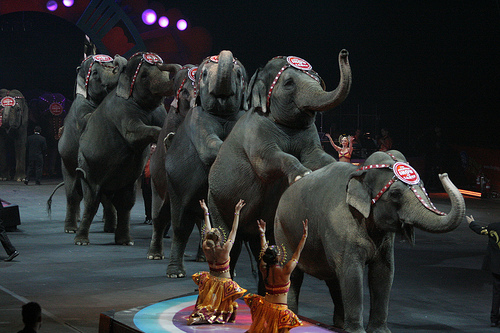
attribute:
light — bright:
[142, 9, 157, 25]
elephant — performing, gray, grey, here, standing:
[46, 53, 128, 235]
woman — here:
[196, 198, 248, 323]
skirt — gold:
[181, 271, 248, 322]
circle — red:
[392, 161, 419, 186]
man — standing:
[27, 125, 50, 184]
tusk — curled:
[420, 172, 465, 234]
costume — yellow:
[181, 260, 247, 323]